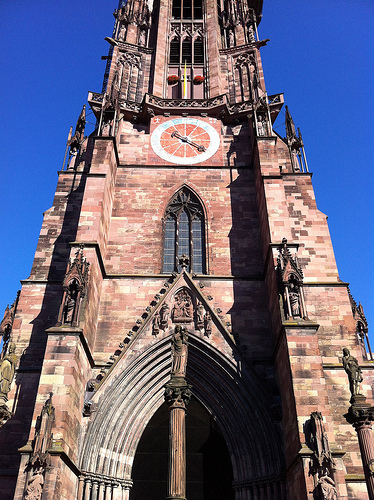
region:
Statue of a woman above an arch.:
[170, 323, 189, 378]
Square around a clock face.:
[149, 116, 224, 166]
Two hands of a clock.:
[172, 129, 207, 152]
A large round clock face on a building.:
[152, 118, 219, 164]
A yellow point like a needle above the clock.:
[182, 59, 187, 98]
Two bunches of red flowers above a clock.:
[165, 74, 205, 84]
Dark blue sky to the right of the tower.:
[258, 2, 372, 348]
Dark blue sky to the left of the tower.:
[1, 1, 118, 301]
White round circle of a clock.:
[150, 114, 220, 166]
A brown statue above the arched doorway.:
[169, 325, 188, 386]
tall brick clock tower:
[4, 2, 371, 498]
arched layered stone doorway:
[74, 322, 287, 498]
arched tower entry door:
[72, 252, 291, 498]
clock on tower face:
[144, 114, 224, 165]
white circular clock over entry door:
[149, 113, 223, 173]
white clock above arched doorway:
[146, 115, 222, 168]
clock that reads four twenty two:
[149, 115, 220, 168]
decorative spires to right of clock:
[281, 103, 314, 173]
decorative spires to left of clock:
[56, 104, 93, 171]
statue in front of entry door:
[164, 323, 195, 384]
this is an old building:
[73, 327, 108, 375]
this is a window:
[160, 260, 177, 279]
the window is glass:
[171, 253, 188, 294]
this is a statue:
[164, 324, 192, 391]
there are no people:
[122, 359, 235, 497]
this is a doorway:
[136, 420, 210, 476]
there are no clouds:
[2, 264, 3, 265]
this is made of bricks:
[260, 342, 313, 411]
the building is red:
[301, 381, 318, 422]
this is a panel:
[147, 274, 189, 315]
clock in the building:
[152, 108, 226, 172]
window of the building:
[154, 183, 214, 277]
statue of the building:
[342, 346, 368, 405]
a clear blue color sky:
[310, 53, 358, 159]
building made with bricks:
[95, 170, 139, 252]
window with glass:
[165, 217, 208, 268]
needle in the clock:
[172, 125, 208, 151]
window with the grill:
[170, 30, 209, 67]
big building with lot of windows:
[90, 22, 298, 482]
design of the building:
[111, 39, 153, 108]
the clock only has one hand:
[147, 111, 229, 168]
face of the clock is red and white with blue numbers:
[151, 115, 220, 167]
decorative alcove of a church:
[101, 252, 272, 498]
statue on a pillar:
[339, 346, 371, 455]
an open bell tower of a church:
[154, 0, 219, 98]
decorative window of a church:
[158, 178, 209, 273]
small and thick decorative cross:
[176, 252, 190, 268]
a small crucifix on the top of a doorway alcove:
[178, 254, 187, 268]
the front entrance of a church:
[5, 46, 372, 457]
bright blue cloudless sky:
[11, 28, 50, 148]